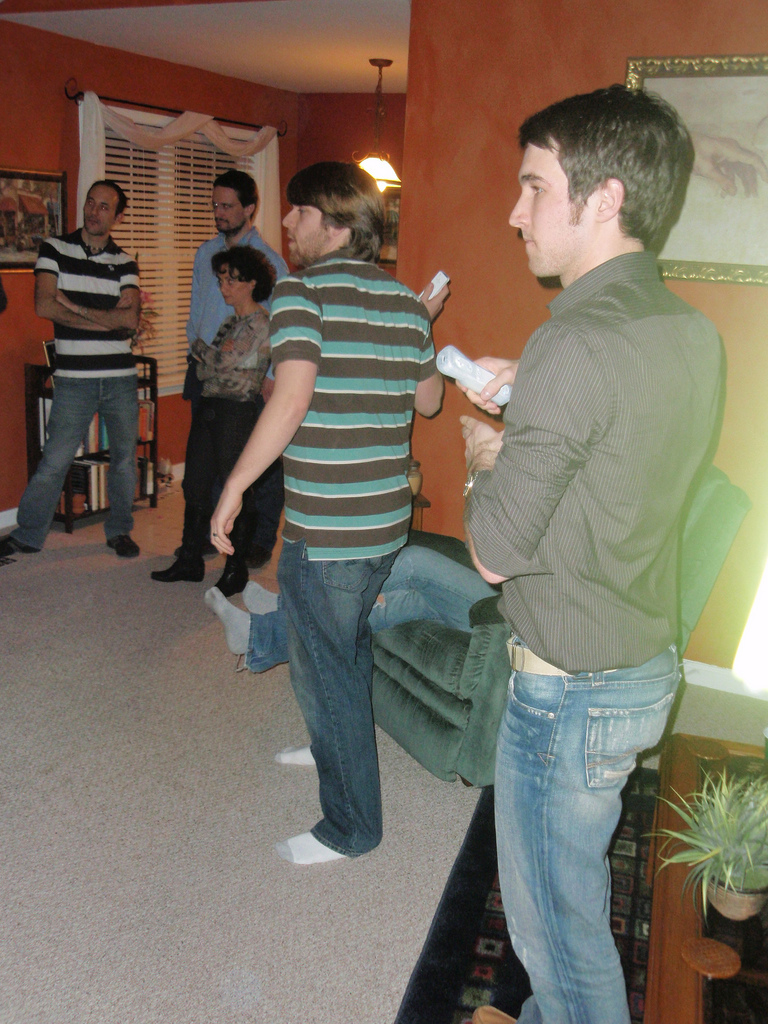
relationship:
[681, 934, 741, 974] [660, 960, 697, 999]
coaster on table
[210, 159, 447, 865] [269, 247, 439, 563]
man has shirt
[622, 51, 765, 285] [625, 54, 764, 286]
frame around frame